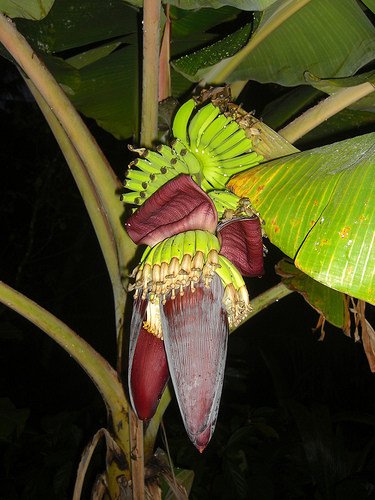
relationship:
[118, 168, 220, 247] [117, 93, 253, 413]
petal under fruit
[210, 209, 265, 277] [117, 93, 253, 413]
petal under fruit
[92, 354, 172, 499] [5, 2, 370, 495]
trunk of tree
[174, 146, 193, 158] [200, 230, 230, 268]
tip on banana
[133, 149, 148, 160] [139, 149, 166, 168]
black tip on banana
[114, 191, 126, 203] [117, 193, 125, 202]
tip on banana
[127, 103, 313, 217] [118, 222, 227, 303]
banana on bunch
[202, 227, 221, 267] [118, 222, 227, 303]
banana on bunch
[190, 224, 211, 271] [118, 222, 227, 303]
banana on bunch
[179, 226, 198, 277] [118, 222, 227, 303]
banana on bunch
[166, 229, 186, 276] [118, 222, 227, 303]
banana on bunch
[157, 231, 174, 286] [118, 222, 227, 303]
banana on bunch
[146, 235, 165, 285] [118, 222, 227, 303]
banana on bunch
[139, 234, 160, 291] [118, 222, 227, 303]
banana on bunch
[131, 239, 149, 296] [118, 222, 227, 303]
banana on bunch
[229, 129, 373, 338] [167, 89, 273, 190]
leaf on bunch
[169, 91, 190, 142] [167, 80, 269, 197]
banana in bunch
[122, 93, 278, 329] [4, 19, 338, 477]
bananas on tree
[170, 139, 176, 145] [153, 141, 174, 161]
black tip on banana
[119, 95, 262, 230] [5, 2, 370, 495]
bananas on tree